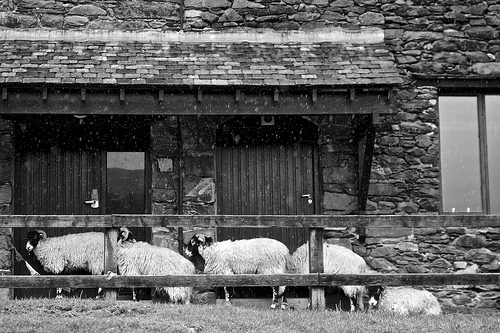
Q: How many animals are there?
A: Five.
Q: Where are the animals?
A: Outside of a building.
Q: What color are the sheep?
A: White with dark faces.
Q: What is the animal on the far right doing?
A: Laying down.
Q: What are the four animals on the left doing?
A: Standing.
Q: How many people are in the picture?
A: Zero.